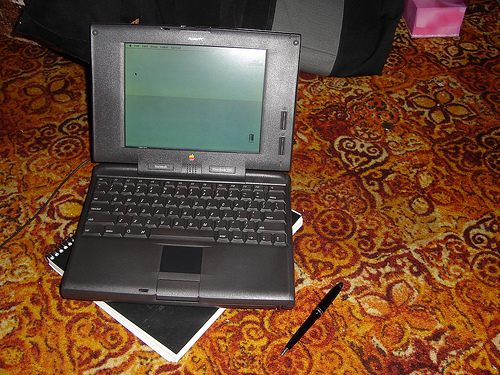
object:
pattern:
[2, 0, 500, 375]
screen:
[120, 41, 267, 154]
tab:
[132, 42, 142, 48]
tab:
[139, 43, 150, 48]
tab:
[148, 45, 159, 49]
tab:
[160, 45, 170, 49]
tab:
[168, 44, 181, 50]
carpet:
[350, 291, 471, 364]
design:
[404, 88, 467, 125]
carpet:
[326, 102, 475, 184]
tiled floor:
[341, 73, 499, 373]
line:
[87, 24, 303, 38]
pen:
[282, 277, 348, 358]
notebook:
[44, 207, 305, 363]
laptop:
[58, 22, 302, 310]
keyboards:
[81, 177, 287, 242]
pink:
[408, 2, 465, 40]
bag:
[9, 0, 418, 82]